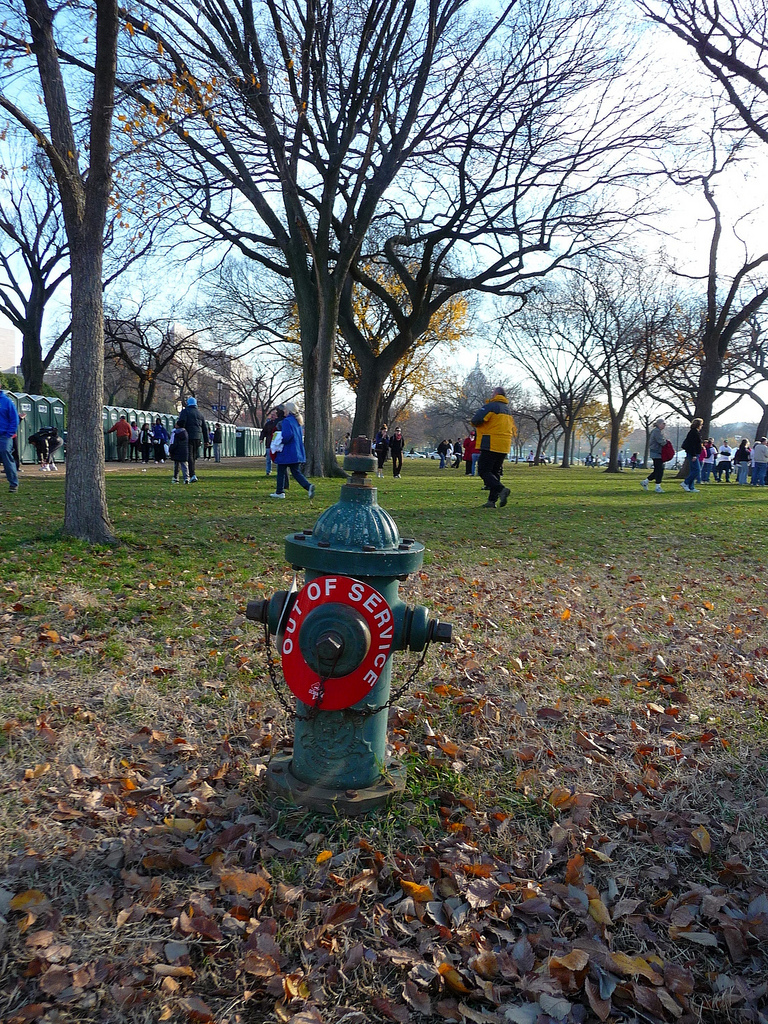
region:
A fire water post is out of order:
[249, 420, 456, 828]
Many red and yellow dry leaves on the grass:
[121, 825, 660, 999]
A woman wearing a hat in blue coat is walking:
[266, 399, 314, 503]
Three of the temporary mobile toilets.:
[14, 392, 67, 470]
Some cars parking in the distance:
[401, 443, 442, 466]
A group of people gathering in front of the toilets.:
[106, 418, 177, 465]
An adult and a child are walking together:
[152, 386, 214, 493]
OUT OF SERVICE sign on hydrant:
[278, 576, 394, 717]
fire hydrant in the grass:
[251, 472, 445, 809]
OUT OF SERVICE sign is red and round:
[281, 577, 384, 707]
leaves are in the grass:
[209, 852, 628, 972]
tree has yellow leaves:
[270, 252, 457, 471]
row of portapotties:
[2, 384, 294, 467]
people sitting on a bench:
[524, 443, 556, 466]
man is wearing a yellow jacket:
[467, 385, 515, 502]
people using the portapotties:
[107, 409, 173, 469]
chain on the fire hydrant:
[262, 606, 423, 725]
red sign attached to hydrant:
[275, 577, 402, 711]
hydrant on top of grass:
[247, 431, 442, 821]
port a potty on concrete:
[18, 395, 43, 466]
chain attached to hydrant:
[255, 627, 339, 724]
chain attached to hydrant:
[350, 614, 455, 723]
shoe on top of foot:
[494, 483, 515, 506]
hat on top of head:
[186, 395, 201, 409]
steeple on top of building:
[468, 351, 482, 368]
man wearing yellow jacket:
[467, 384, 519, 456]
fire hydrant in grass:
[238, 429, 461, 827]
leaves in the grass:
[7, 817, 759, 1019]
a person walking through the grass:
[467, 383, 516, 512]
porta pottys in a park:
[0, 386, 266, 461]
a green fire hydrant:
[244, 431, 459, 820]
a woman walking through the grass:
[270, 404, 320, 501]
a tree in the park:
[7, 0, 145, 550]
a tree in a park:
[142, 2, 653, 472]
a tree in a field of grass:
[494, 239, 600, 483]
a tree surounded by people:
[563, 397, 636, 473]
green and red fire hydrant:
[235, 432, 455, 816]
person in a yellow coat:
[464, 387, 516, 506]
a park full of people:
[5, 391, 766, 1015]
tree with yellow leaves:
[287, 263, 477, 472]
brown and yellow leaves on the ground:
[13, 811, 755, 1022]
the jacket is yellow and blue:
[472, 392, 521, 455]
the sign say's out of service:
[279, 575, 393, 709]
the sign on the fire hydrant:
[246, 431, 452, 816]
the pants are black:
[477, 448, 505, 499]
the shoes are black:
[481, 487, 512, 511]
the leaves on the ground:
[1, 453, 766, 1021]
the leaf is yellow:
[609, 948, 663, 983]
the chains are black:
[257, 619, 432, 722]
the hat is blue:
[183, 393, 197, 403]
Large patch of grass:
[557, 474, 627, 535]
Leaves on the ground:
[153, 841, 699, 1020]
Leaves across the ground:
[157, 823, 675, 1022]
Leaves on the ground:
[6, 689, 224, 834]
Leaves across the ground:
[72, 818, 352, 1020]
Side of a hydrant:
[401, 607, 456, 653]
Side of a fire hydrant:
[403, 597, 460, 657]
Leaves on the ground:
[375, 845, 680, 1019]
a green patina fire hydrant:
[240, 431, 455, 784]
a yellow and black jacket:
[469, 394, 512, 454]